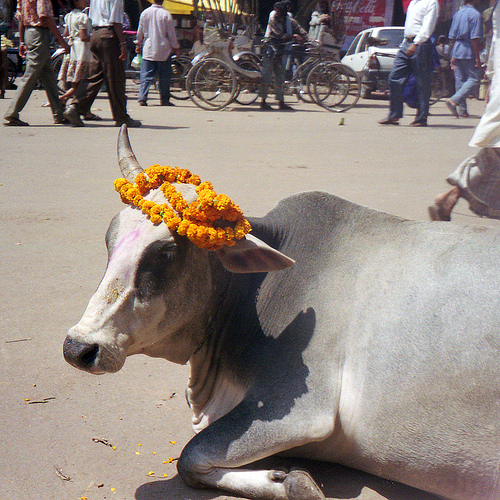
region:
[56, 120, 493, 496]
Large animal on the ground.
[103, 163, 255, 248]
Flower on the animal.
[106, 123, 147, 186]
Horn on the animal.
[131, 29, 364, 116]
Bicycles in the background.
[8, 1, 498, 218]
People walking in the background.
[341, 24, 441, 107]
White car in the background.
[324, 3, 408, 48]
Advertising for Coke in the background.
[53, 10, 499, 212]
Women in dresses in the street.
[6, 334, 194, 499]
Dirt and flowers on the ground.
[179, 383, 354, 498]
Leg of animal folded over.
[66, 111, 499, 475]
A cow sitting on the road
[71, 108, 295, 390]
Orange marigold garland on cow's head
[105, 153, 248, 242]
Orange flower garland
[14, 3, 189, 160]
People walking on the street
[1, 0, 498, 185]
Busy street in the city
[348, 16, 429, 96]
White car parked on the road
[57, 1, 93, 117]
A girl wearing a white dress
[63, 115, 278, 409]
A cow with one horn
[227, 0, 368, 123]
A person holding a bicycle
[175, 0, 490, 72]
Shops on the other side of the road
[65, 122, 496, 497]
A cow is lying down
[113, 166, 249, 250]
The wreath is orange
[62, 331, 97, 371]
The cow has a black nose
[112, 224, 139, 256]
Something purple on the cow's head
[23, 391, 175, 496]
Debris on the street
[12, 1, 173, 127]
People walking around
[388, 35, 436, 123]
The pants are blue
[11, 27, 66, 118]
The pants are gray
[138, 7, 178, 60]
The shirt is white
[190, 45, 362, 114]
A couple of bikes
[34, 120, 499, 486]
large cow laying on ground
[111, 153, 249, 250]
string of flowers on cows head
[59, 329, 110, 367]
black nose on cow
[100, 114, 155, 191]
horn on cows head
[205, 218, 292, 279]
ear on large cow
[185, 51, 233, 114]
tire of bicycle on street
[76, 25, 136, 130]
brown pants on man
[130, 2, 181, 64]
white shirt on man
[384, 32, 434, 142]
jeans on man walking on street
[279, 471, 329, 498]
hoof of large cow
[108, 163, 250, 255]
orange flowers on animals head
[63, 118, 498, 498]
cow is laying on ground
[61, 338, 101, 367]
cow has black nose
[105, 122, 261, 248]
cow has one horn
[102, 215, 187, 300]
animal has dark circles around eyes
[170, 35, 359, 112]
several bicycles in background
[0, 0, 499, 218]
people walk behind cow on street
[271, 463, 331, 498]
the cow has hooves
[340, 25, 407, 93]
the car is white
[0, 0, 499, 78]
buildings behind people on street